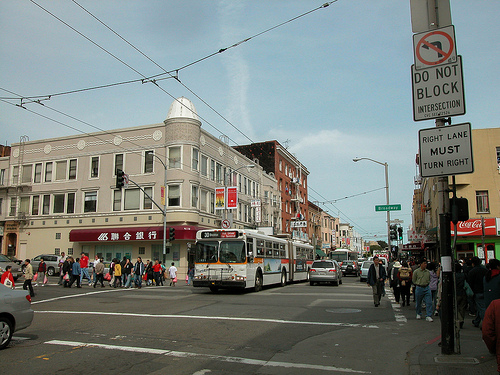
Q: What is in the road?
A: A bus.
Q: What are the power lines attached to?
A: The poles.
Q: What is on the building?
A: Assorted signs.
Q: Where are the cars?
A: In the road.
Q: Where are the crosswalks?
A: In the street.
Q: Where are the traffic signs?
A: On the pole.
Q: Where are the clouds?
A: In the sky.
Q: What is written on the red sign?
A: Coca cola.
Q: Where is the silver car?
A: Next to the bus.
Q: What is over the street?
A: A power line.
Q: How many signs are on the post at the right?
A: Three.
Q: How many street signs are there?
A: One.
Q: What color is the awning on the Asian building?
A: Dark red.